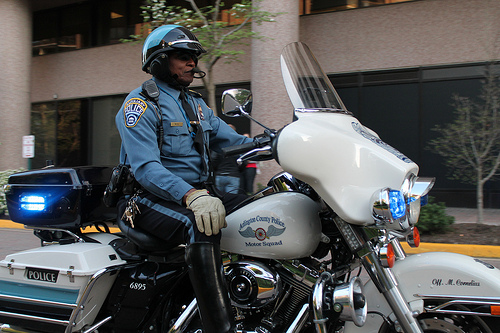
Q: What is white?
A: Motorcycle.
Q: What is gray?
A: Gloves.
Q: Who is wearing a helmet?
A: Police officer.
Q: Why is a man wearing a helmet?
A: Man is riding a motorbike.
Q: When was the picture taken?
A: Daytime.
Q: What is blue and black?
A: Helmet.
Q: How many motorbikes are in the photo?
A: One.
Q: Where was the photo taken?
A: On the road.